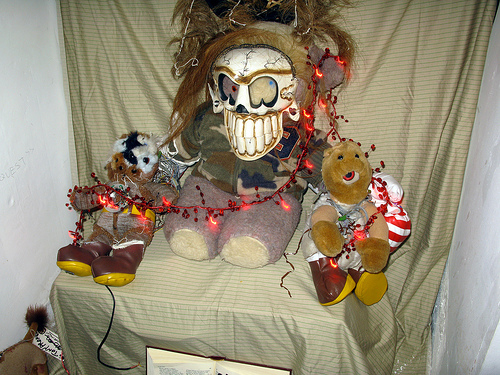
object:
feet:
[216, 226, 274, 270]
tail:
[22, 307, 47, 340]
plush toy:
[21, 304, 65, 360]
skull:
[205, 19, 300, 162]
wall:
[446, 4, 500, 374]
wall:
[0, 0, 55, 351]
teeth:
[253, 120, 263, 137]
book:
[145, 344, 292, 375]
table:
[52, 225, 349, 374]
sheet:
[48, 0, 498, 374]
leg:
[217, 191, 305, 268]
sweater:
[304, 197, 370, 264]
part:
[346, 256, 356, 265]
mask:
[156, 0, 357, 162]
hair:
[159, 0, 361, 149]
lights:
[278, 197, 292, 211]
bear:
[300, 142, 391, 308]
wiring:
[95, 285, 142, 372]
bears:
[55, 129, 181, 287]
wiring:
[91, 45, 326, 212]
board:
[56, 204, 351, 328]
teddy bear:
[156, 21, 345, 268]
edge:
[118, 290, 307, 323]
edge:
[336, 246, 353, 260]